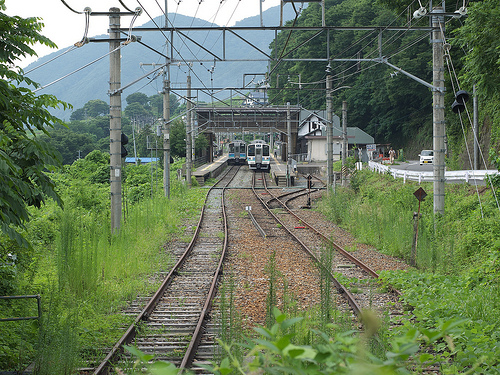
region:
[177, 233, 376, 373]
weeds between train tracks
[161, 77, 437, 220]
a rural train station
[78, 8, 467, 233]
two supporting poles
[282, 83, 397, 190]
a rural train depot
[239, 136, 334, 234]
a side track for a train car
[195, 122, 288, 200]
two trains meeting at the station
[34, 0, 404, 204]
mountains in the distance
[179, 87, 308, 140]
an overhead cover for the passengers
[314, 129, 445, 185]
a single car at the station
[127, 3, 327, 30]
wires suspended overhead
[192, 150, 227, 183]
concrete train station platform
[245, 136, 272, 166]
white train in the station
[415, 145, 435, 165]
white sedan traveling on the street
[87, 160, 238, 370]
rusty old brown train tracks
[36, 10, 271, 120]
large mountain behind train station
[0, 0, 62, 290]
tall green tree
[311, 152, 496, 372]
overgrown green weeds and grass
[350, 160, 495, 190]
white painted metal road divider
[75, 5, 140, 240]
wooden utility beam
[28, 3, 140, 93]
electrical wires attached to wooden beam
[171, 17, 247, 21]
suspended power lines for a train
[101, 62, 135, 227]
pole with brackets around it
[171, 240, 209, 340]
metal train tracks with wood ties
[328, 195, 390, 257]
tall grass by a train track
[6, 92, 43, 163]
green leaves on a tree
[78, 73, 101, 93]
trees on a mountain side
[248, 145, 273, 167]
the front of a train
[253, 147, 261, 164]
the door on a train car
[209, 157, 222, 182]
a train loading platform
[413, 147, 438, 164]
a white car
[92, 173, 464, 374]
Train tracks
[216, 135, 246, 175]
Blue train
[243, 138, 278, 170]
White train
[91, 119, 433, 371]
Two trains riding down the train tracks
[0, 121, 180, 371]
Green grass on the side of the train tracks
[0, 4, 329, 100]
Mountains in the background of the train tracks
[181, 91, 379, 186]
Two trains passing by the train station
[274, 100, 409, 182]
Train station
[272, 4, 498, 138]
Huge green trees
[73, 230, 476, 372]
Grass growing through the train tracks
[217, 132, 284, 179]
Two trains traveling under a bridge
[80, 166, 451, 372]
Two rails of train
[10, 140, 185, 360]
Weeds on left side of rails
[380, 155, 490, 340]
Weeds on right side of rails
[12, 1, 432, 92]
Electric wires over the rails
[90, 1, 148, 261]
Pole holding electric wires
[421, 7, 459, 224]
Pole holding electric wires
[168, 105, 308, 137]
Bridge over the rails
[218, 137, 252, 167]
Train is blue and white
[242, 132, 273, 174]
Train is white